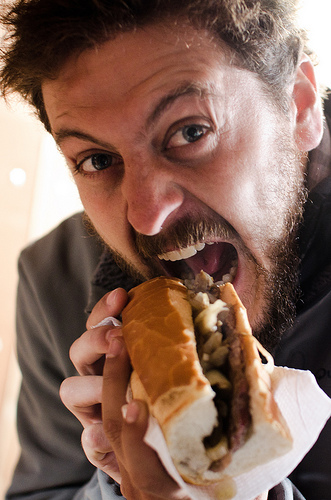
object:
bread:
[119, 274, 218, 485]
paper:
[143, 364, 330, 499]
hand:
[59, 286, 128, 484]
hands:
[57, 285, 128, 486]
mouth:
[144, 235, 242, 298]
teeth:
[180, 244, 197, 259]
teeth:
[223, 274, 234, 284]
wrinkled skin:
[202, 90, 233, 132]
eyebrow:
[144, 78, 216, 133]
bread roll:
[121, 276, 217, 484]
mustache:
[136, 212, 231, 264]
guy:
[0, 0, 330, 498]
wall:
[35, 128, 80, 252]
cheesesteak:
[121, 269, 293, 485]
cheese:
[195, 298, 228, 332]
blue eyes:
[164, 114, 214, 150]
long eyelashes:
[68, 154, 95, 176]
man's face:
[43, 27, 279, 329]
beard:
[82, 152, 317, 360]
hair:
[0, 3, 320, 138]